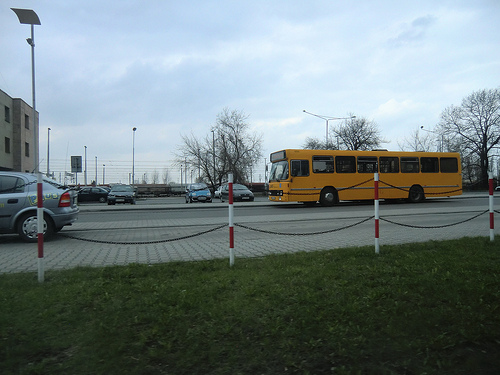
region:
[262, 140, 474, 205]
A yellow bus parked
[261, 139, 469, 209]
A yellow passenger bus parked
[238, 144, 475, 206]
A bus parked in a parking lot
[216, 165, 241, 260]
A pole painted red and white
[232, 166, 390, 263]
Red & white poles with chains between them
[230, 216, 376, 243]
Chain draped between poles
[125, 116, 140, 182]
Tall lights in a parking lot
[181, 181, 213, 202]
A very small blue car parked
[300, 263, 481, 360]
Very green bushes on this side of fence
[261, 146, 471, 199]
The bus is yellow and long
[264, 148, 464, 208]
a yellow bus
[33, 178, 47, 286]
a red and white post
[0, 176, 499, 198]
a chain connecting the red and white posts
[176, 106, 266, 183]
a tree with no leaves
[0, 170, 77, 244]
the back end of a gray car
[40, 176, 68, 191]
rear windshield wiper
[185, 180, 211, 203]
a blue car parked in a lot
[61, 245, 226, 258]
a section of brick pavers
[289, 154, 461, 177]
a row of windows on a bus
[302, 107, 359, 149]
two overhead lights on a light pole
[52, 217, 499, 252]
Chain on the poles.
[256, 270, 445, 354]
The grass is green.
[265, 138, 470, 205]
The bus is yellow.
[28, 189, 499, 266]
The poles are white and red.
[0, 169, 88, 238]
Car on the side of the road.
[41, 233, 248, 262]
The sidewalk is brick.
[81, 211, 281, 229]
The meridian is brick.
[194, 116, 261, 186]
No leaves on the trees.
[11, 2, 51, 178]
Light pole in the corner.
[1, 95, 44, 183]
The building is brown.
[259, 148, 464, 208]
A long yellow bus.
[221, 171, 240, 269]
A skinny red and white pole.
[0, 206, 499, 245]
A metal chain connecting poles.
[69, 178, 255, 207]
A group of parked cars.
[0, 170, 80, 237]
The tail end of a light blue car.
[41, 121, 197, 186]
Multiple light poles.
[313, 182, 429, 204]
The wheels on a bus.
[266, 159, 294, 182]
The windshield of a bus.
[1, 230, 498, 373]
A patch of green grass beside a road.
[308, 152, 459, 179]
Seven windows in a row.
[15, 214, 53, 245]
A back wheel of the silver car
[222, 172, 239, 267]
A red and white pole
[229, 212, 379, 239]
A chain link between two red-white poles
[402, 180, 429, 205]
The back wheel of a school bus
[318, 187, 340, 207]
The front wheel of a school bus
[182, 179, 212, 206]
A parked blue mini car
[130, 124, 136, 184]
A tall standing pole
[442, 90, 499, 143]
The top portions of a tree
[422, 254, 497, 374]
The bottom right portion of a patch of grass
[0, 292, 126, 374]
The bottom left portion of a patch of grass